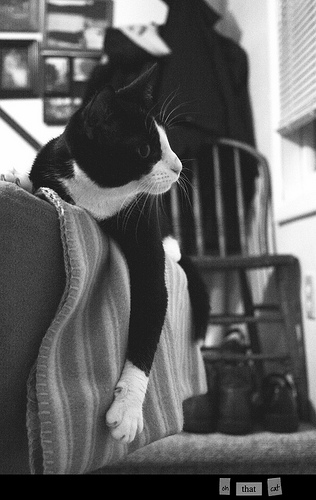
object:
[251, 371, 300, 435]
boots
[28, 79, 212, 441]
cat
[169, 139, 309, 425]
chair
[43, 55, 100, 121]
picture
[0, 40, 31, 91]
family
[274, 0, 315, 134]
blinds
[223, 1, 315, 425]
wall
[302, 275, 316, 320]
socket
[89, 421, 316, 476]
carpet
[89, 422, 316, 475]
brown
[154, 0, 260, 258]
coat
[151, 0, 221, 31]
coat hanger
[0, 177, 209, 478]
couch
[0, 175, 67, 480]
armrest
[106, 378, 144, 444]
paws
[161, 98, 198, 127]
whiskers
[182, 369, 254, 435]
shoes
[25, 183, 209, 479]
towell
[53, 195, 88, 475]
lines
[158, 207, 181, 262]
leg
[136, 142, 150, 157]
eye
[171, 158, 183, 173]
nose